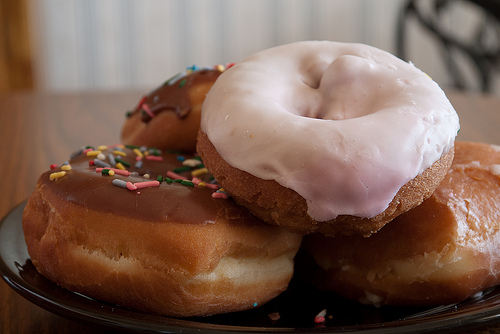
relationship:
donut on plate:
[195, 39, 462, 242] [3, 191, 500, 334]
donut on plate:
[307, 138, 497, 312] [3, 191, 500, 334]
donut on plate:
[23, 141, 305, 320] [3, 191, 500, 334]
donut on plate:
[117, 63, 232, 157] [3, 191, 500, 334]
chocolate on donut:
[129, 65, 222, 124] [117, 63, 232, 157]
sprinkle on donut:
[134, 180, 163, 191] [23, 141, 305, 320]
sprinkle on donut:
[111, 177, 128, 189] [23, 141, 305, 320]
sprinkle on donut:
[180, 178, 196, 187] [23, 141, 305, 320]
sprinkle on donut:
[47, 171, 67, 184] [23, 141, 305, 320]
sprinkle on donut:
[142, 103, 155, 122] [117, 63, 232, 157]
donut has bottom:
[23, 141, 305, 320] [22, 220, 300, 321]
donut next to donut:
[195, 39, 462, 242] [307, 138, 497, 312]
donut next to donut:
[307, 138, 497, 312] [23, 141, 305, 320]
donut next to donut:
[23, 141, 305, 320] [117, 63, 232, 157]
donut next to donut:
[117, 63, 232, 157] [195, 39, 462, 242]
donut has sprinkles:
[23, 141, 305, 320] [48, 142, 233, 203]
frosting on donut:
[39, 145, 256, 227] [23, 141, 305, 320]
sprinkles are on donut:
[48, 142, 233, 203] [23, 141, 305, 320]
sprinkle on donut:
[108, 167, 134, 178] [23, 141, 305, 320]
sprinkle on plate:
[314, 315, 326, 323] [3, 191, 500, 334]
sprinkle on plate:
[267, 311, 281, 321] [3, 191, 500, 334]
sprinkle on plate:
[316, 308, 328, 317] [3, 191, 500, 334]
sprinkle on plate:
[327, 312, 334, 319] [3, 191, 500, 334]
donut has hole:
[195, 39, 462, 242] [279, 79, 387, 131]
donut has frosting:
[195, 39, 462, 242] [197, 39, 463, 225]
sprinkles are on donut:
[124, 60, 238, 119] [117, 63, 232, 157]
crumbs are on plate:
[264, 304, 336, 326] [3, 191, 500, 334]